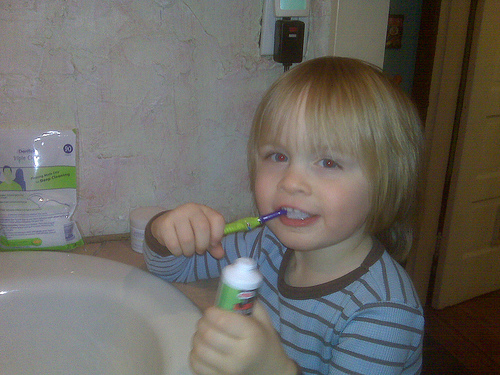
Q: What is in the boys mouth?
A: Toothbrush.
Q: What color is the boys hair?
A: Blonde.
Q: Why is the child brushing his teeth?
A: To clean them.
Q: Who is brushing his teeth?
A: The boy.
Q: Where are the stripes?
A: On the boys shirt.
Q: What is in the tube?
A: Toothpaste.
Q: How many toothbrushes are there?
A: One.